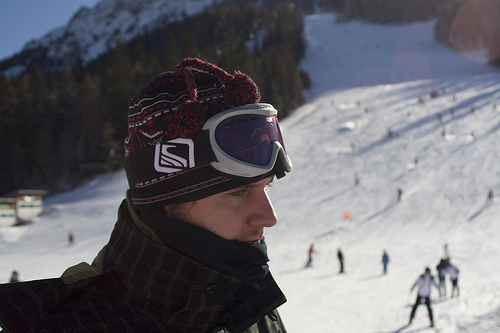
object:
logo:
[150, 135, 192, 179]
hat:
[118, 54, 297, 209]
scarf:
[120, 208, 280, 304]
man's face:
[175, 179, 285, 251]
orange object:
[333, 205, 360, 230]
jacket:
[3, 207, 294, 329]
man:
[1, 54, 293, 332]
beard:
[237, 228, 266, 241]